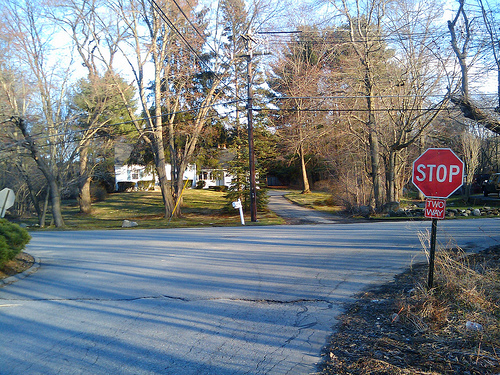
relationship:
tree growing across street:
[6, 1, 117, 230] [13, 218, 496, 273]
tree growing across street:
[71, 2, 225, 221] [13, 218, 496, 273]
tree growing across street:
[271, 21, 338, 196] [13, 218, 496, 273]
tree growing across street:
[328, 3, 442, 215] [13, 218, 496, 273]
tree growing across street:
[381, 6, 455, 207] [13, 218, 496, 273]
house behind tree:
[112, 135, 266, 195] [71, 2, 225, 221]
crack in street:
[4, 295, 351, 312] [13, 218, 496, 273]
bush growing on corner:
[1, 218, 32, 264] [3, 246, 43, 284]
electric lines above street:
[0, 2, 498, 157] [13, 218, 496, 273]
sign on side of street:
[412, 148, 465, 199] [13, 218, 496, 273]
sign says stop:
[412, 148, 465, 199] [418, 162, 456, 186]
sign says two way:
[425, 197, 446, 220] [425, 198, 443, 217]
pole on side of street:
[246, 18, 257, 222] [13, 218, 496, 273]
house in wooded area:
[112, 135, 266, 195] [41, 137, 284, 227]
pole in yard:
[241, 18, 259, 222] [44, 183, 269, 225]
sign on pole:
[425, 197, 446, 220] [423, 213, 440, 285]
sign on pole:
[412, 146, 461, 198] [423, 213, 440, 285]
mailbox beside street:
[230, 198, 245, 225] [13, 218, 496, 273]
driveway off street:
[258, 183, 349, 221] [13, 218, 496, 273]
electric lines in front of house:
[0, 2, 498, 157] [112, 135, 266, 195]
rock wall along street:
[407, 202, 498, 220] [13, 218, 496, 273]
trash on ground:
[462, 318, 486, 337] [330, 238, 495, 374]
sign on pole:
[412, 148, 465, 199] [423, 213, 440, 285]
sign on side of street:
[425, 197, 446, 220] [13, 218, 496, 273]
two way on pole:
[425, 198, 443, 217] [423, 213, 440, 285]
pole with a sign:
[423, 213, 440, 285] [412, 148, 465, 199]